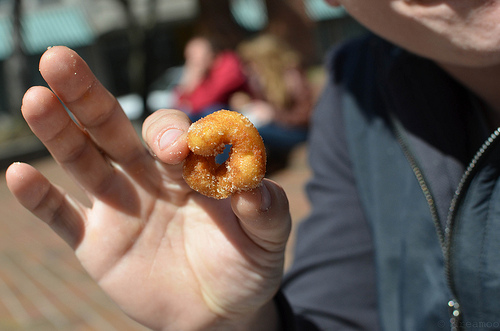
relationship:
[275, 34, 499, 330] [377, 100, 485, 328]
jacket with zipper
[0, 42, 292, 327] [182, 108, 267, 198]
hand holding doughnut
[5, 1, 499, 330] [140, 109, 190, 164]
man has finger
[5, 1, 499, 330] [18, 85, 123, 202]
man has finger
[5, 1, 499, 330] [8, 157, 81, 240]
man has finger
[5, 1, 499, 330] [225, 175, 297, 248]
man has thumb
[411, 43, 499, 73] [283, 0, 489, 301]
jaw of person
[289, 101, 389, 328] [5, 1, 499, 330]
arm of man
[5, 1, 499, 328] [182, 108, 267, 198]
man showing off an oddly shaped doughnut